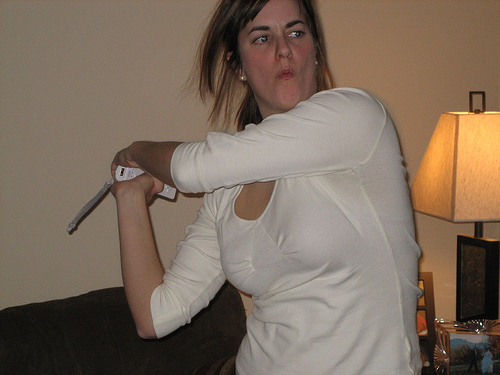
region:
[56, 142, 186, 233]
The is holding a wii controller in hand.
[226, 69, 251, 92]
The lady is wearing earrings.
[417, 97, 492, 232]
The lamp shade is white.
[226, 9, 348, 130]
The lady is making strange faces.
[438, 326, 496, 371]
A picture frame on the table.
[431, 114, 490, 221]
The light is shining through the shade.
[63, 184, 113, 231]
A string on the end of controller.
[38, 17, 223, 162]
The wall is beige.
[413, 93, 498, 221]
a lamp shade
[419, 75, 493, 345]
a lamp on the table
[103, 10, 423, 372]
a lady wearing a white shirt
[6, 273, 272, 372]
a sofa behind the lady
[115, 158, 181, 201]
a white game remote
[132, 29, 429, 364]
a lady swinging her arms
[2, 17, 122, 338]
the wall behind the lady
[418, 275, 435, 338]
a picture frame on the table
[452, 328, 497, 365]
a picture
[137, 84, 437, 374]
Woman is wearing a shirt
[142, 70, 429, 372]
Woman wearing a white shirt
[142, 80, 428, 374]
Woman is wearing a white shirt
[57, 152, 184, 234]
Woman holding a controller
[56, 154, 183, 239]
Woman is holding a controller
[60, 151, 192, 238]
Woman holding a video game controller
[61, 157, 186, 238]
Woman is holding a video game controller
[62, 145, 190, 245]
Woman holding a Nintendo Wii controller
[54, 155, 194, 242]
Woman is holding a Nintendo Wii controller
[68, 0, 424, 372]
Woman holding a Wii remote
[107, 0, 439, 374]
Woman wearing a white shirt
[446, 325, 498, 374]
Photo of a bride and a groom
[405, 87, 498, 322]
Wood table lamp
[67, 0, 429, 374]
Woman playing video games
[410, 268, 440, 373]
Black wood frame with photos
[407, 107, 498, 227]
White cloth lampshade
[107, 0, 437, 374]
Woman with pursed lips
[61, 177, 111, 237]
Gray wrist band on a Wii remote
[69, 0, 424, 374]
A woman playing a video game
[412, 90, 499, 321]
A dark colored table lamp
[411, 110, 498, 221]
A squared off lamp shade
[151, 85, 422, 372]
A woman's white shirt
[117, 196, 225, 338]
A woman's right arm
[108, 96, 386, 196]
A woman's left arm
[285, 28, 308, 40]
A woman's left eye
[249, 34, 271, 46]
A woman's right eye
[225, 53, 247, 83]
A woman's right ear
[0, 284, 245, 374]
A brown couch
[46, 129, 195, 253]
nintendo wii remote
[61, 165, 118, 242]
grey nintendo wii strap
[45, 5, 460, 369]
woman playing nintendo wii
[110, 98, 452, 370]
white three quarter sleeve shirt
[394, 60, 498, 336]
lamp on a table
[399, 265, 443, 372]
edge of a wooden chair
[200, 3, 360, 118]
women wearing earrings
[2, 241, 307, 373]
dark colored couch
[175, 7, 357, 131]
women with medium length hair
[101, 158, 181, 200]
woman holding a Wii controller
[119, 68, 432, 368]
woman wearing a white shirt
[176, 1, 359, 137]
woman with blonde hair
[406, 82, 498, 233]
White shade on the lamp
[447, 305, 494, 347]
ashtray on the table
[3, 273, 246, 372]
brown sofa behind the woman